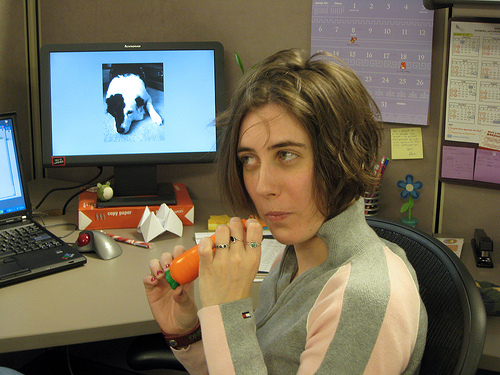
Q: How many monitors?
A: 2.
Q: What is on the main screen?
A: Dog.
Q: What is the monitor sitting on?
A: Book.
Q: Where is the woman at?
A: Work.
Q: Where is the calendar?
A: Behind the woman.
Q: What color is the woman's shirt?
A: Gray and pink.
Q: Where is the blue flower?
A: To the right.